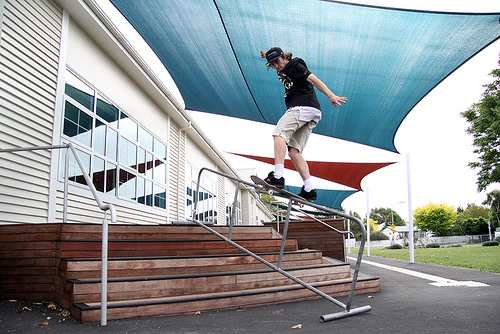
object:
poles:
[406, 152, 415, 265]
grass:
[351, 240, 500, 274]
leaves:
[4, 296, 75, 326]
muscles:
[268, 130, 323, 184]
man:
[257, 47, 348, 204]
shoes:
[256, 171, 318, 201]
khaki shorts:
[271, 105, 322, 155]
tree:
[415, 203, 492, 238]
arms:
[262, 49, 334, 98]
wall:
[0, 0, 285, 229]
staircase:
[58, 221, 378, 324]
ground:
[0, 256, 499, 334]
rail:
[170, 165, 372, 322]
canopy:
[109, 0, 500, 157]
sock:
[274, 163, 286, 179]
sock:
[298, 177, 318, 193]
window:
[62, 82, 168, 210]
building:
[0, 0, 383, 316]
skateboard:
[250, 174, 316, 208]